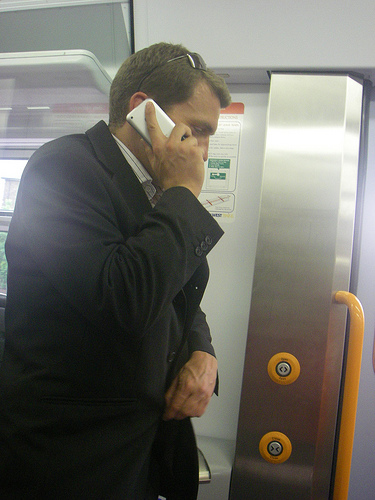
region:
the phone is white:
[124, 100, 173, 147]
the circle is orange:
[258, 429, 288, 461]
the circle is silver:
[267, 440, 281, 456]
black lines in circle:
[278, 365, 289, 374]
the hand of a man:
[164, 351, 215, 421]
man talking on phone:
[113, 41, 231, 197]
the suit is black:
[2, 119, 223, 497]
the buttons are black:
[195, 234, 211, 254]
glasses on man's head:
[139, 48, 203, 90]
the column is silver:
[227, 72, 362, 497]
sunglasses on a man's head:
[137, 49, 211, 91]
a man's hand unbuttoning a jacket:
[165, 352, 218, 420]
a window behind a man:
[0, 226, 12, 295]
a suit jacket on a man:
[0, 118, 221, 498]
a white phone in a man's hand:
[126, 99, 178, 145]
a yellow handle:
[325, 290, 373, 498]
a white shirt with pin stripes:
[113, 133, 164, 208]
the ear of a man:
[128, 89, 148, 112]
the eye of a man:
[191, 123, 206, 135]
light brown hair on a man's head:
[106, 43, 232, 130]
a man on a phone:
[108, 64, 282, 222]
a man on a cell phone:
[104, 5, 257, 179]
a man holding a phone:
[93, 73, 247, 188]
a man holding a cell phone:
[87, 7, 262, 240]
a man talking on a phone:
[94, 12, 281, 224]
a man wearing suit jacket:
[39, 95, 225, 419]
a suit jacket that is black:
[56, 182, 223, 458]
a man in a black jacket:
[0, 39, 234, 498]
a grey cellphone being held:
[124, 96, 184, 142]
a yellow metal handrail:
[330, 287, 365, 498]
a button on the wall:
[265, 352, 300, 383]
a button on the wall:
[257, 428, 291, 463]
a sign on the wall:
[196, 102, 244, 225]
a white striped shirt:
[113, 135, 158, 207]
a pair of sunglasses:
[135, 51, 210, 91]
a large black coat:
[2, 118, 225, 498]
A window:
[1, 152, 29, 298]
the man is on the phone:
[125, 100, 188, 157]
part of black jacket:
[139, 448, 194, 492]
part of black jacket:
[65, 438, 129, 489]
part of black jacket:
[0, 455, 52, 496]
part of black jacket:
[4, 398, 59, 434]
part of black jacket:
[73, 399, 128, 433]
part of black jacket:
[8, 335, 57, 389]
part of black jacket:
[82, 316, 136, 366]